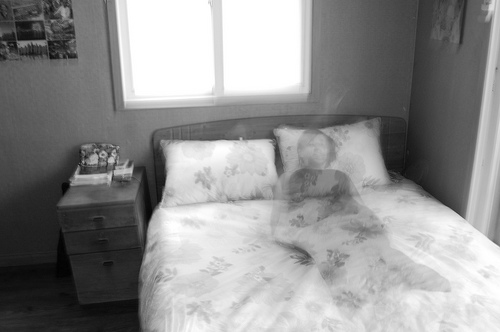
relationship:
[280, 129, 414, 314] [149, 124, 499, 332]
figure on top of bed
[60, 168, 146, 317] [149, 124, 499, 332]
nightstand beside bed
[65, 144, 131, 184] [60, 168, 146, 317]
items on top of nightstand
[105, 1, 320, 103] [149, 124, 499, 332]
window above bed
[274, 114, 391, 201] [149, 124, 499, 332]
right pillow on top of bed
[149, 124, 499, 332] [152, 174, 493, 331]
bed with sheets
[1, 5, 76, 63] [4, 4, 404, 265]
pictures on side of wall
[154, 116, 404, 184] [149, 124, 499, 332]
headboard of bed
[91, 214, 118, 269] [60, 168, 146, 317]
pulls on front of nightstand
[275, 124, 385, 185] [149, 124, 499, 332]
left pillow on top of bed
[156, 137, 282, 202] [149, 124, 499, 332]
right pillow of bed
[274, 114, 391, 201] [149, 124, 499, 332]
right pillow propped on bed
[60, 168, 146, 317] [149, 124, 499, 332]
nightstand by bed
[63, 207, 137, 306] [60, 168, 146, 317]
drawers of nightstand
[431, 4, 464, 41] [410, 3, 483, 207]
artwork on side of wall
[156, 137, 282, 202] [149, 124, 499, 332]
pillow on top of bed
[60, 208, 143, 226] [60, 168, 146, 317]
drawer in nightstand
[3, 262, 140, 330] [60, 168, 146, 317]
floor under nightstand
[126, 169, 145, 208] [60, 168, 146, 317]
edge of nightstand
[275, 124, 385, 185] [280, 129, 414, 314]
pillow with figure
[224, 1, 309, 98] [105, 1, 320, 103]
right pane of window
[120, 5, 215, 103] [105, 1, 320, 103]
left pane of window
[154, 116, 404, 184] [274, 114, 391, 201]
headboard with right pillow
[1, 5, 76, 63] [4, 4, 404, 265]
pictures on front of wall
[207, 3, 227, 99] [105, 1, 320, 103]
divider of window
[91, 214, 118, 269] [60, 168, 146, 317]
handles on front of nightstand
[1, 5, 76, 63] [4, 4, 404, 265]
pictures hanging on wall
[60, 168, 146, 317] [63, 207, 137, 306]
nightstand with drawers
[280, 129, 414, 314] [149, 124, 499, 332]
figure laying on bed